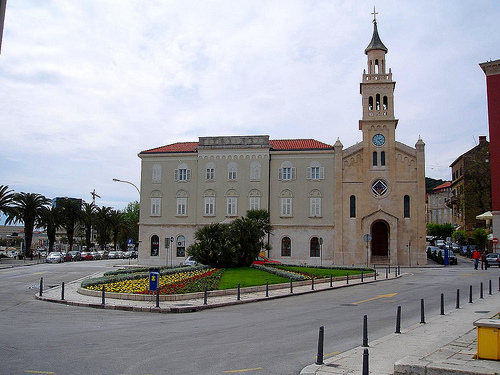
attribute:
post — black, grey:
[154, 287, 161, 307]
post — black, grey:
[101, 284, 105, 303]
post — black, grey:
[61, 281, 67, 303]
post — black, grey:
[38, 275, 44, 299]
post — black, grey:
[203, 286, 208, 308]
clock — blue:
[371, 132, 388, 149]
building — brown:
[136, 6, 430, 269]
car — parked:
[439, 248, 458, 267]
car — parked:
[44, 249, 64, 263]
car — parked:
[59, 249, 74, 264]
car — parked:
[70, 249, 83, 261]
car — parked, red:
[81, 250, 94, 261]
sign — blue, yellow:
[147, 270, 160, 292]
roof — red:
[141, 136, 334, 155]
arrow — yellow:
[349, 290, 397, 303]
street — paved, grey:
[1, 257, 500, 374]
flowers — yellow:
[86, 267, 212, 292]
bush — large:
[189, 208, 273, 266]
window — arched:
[280, 166, 293, 180]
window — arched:
[310, 167, 321, 180]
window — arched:
[251, 163, 262, 180]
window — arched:
[227, 166, 238, 180]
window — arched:
[204, 165, 217, 181]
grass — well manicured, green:
[218, 266, 290, 289]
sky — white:
[0, 0, 499, 227]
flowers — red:
[140, 268, 215, 295]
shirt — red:
[472, 251, 482, 260]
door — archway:
[370, 217, 392, 266]